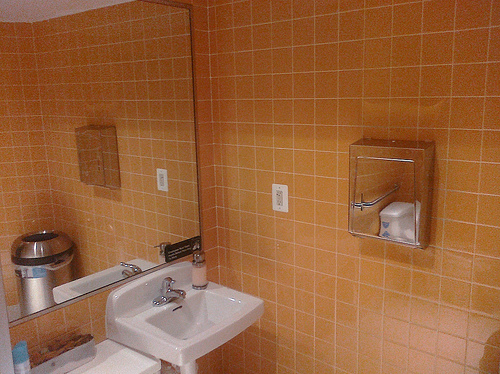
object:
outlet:
[270, 183, 289, 213]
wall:
[209, 0, 499, 374]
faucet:
[152, 276, 186, 306]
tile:
[224, 79, 500, 368]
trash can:
[7, 227, 75, 290]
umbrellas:
[70, 321, 161, 368]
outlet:
[156, 168, 170, 193]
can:
[8, 344, 31, 374]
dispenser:
[347, 138, 432, 246]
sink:
[106, 260, 265, 367]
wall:
[1, 0, 228, 374]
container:
[191, 250, 209, 291]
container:
[346, 137, 437, 250]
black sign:
[163, 234, 200, 262]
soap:
[190, 250, 208, 291]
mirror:
[3, 0, 206, 331]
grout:
[302, 270, 500, 374]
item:
[11, 343, 29, 374]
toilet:
[0, 0, 500, 374]